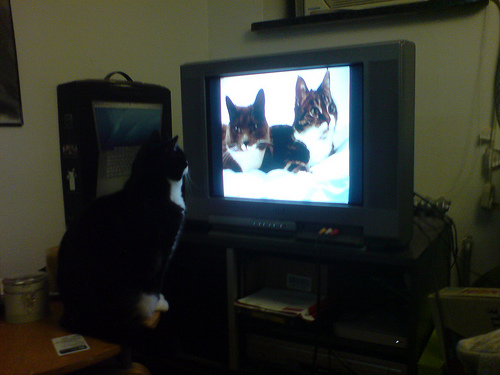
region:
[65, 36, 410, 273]
cat is watching television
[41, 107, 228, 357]
a black and white cat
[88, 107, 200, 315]
a black and white cat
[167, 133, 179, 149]
the brown ear of a cat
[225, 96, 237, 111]
the brown ear of a cat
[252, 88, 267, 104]
the brown ear of a cat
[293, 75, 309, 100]
the brown ear of a cat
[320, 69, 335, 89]
the brown ear of a cat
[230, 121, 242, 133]
the eye of a cat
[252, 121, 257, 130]
the eye of a cat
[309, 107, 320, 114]
the eye of a cat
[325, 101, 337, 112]
the eye of a cat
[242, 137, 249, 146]
the nose of a brown cat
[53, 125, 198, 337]
A cat is perched on a chair.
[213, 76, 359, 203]
Two cats are displayed on the screen.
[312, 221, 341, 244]
Three cables are plugged into the TV>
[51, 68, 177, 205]
A box with a picture of a laptop.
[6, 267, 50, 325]
A small container on a table.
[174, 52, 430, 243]
A large gray television.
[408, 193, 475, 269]
Cables extending from the table.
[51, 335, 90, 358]
A small piece of paper on the table.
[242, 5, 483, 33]
A black shelf above the TV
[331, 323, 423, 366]
A VCR or DVD player.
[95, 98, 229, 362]
this is a cat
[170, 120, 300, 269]
cats are on tv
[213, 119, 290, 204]
these are two cats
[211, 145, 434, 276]
this is a television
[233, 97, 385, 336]
the tv is old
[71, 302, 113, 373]
this is a table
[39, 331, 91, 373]
the table is wooden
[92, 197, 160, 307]
the cat is dark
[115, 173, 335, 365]
this is a living room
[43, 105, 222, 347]
this is a cat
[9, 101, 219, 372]
cat sitting on table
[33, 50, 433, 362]
cat looking at television screen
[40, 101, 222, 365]
cat on table is black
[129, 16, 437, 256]
grey speakers on tv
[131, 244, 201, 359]
white paw on cat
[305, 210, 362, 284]
av cables on tv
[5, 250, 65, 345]
can on table behind cat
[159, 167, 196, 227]
white neck fur on cat